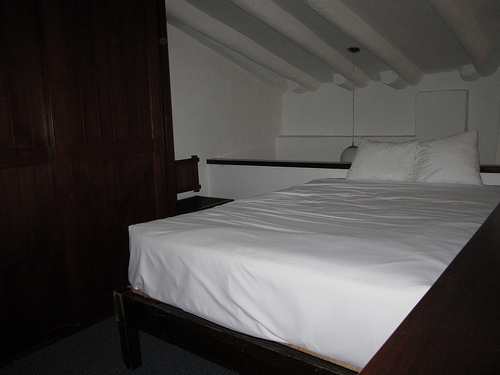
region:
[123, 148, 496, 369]
white sheets on the bed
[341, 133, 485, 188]
two pillows propped up on the bed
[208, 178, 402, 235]
wrinkles in the sheets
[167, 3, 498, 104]
ceiling is sloped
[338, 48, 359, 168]
light fixture hanging down from the ceiling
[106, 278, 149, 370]
small post on the bed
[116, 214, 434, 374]
mattress is thick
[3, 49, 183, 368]
dark brown wood paneling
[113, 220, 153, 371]
corner of the bed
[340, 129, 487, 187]
two white pillows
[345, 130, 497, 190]
Two white pillows on the bed.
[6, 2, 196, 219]
Dark brown wardrobe.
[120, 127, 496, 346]
Single bed in the room.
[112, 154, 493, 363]
Bed covered in white bed sheets.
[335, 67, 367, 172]
Hanging ceiling light.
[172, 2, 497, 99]
Ceiling painted white with beams.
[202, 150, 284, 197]
Banister with a brown top.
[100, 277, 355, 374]
Brown bed frame made of wood.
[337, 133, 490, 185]
Two pillows sitting side by side.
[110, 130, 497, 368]
Bed with no one in it.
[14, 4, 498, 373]
A small and cozy bedroom.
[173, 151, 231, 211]
There is a chair in the room.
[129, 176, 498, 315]
White sheets on the bed.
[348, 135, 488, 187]
Two pillows on the bed.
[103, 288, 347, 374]
Footboard of the bed.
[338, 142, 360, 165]
Overhead light in the shape of a globe.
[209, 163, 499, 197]
A white wall againt the head of the bed.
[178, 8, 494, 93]
There are beams across the roof of the house.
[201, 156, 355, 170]
A dark accent cap against the white wall.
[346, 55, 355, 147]
The chain that holds the globe light up.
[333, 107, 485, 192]
a pillow on a bed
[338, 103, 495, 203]
a white pillow on a bed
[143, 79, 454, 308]
a sheet on a bed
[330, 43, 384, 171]
a light in a room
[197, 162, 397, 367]
a sheet in a room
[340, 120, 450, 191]
a pillow in a room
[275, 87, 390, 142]
a white wall in a room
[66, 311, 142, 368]
carpet in a room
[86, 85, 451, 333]
a bed near a wall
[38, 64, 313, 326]
a wood closet in a room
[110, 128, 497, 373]
Bed in the room.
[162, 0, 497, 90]
white ceiling beams.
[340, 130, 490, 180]
Pillows on the beds.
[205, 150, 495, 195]
half wall in behind the bed.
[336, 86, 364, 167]
light hanging from the ceiling.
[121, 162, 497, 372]
White sheets on bed.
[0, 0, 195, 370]
Dark wardrobe on the wall.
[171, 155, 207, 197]
Picture on the wall.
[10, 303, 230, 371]
Gray coloring on the floor.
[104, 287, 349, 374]
Wood foot board on the bed.